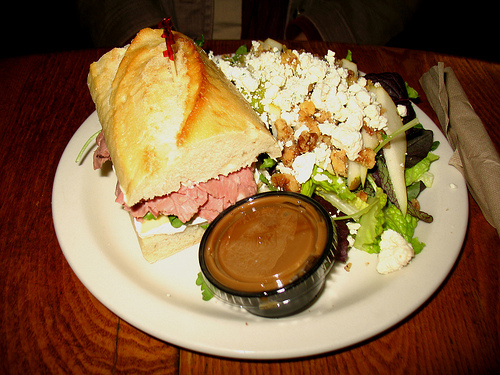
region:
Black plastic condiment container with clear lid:
[195, 188, 335, 318]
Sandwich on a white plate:
[83, 27, 282, 263]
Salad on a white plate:
[263, 39, 435, 267]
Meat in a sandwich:
[128, 167, 262, 224]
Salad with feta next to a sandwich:
[211, 48, 386, 183]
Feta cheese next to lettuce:
[371, 229, 417, 276]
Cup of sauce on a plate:
[201, 193, 337, 320]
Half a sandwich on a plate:
[85, 13, 277, 263]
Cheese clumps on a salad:
[225, 48, 363, 151]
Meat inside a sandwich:
[154, 184, 247, 220]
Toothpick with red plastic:
[159, 13, 179, 79]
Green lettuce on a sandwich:
[151, 212, 186, 231]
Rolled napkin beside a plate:
[430, 56, 499, 228]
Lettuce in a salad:
[358, 198, 423, 243]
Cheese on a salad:
[371, 75, 411, 212]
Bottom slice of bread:
[135, 228, 202, 262]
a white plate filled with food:
[50, 47, 470, 362]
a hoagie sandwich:
[89, 17, 259, 230]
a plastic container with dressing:
[202, 194, 335, 316]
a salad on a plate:
[217, 52, 424, 245]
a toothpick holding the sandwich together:
[160, 18, 181, 75]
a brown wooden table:
[5, 31, 499, 374]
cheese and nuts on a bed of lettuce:
[230, 49, 409, 199]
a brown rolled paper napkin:
[424, 56, 497, 228]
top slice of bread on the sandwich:
[96, 27, 271, 198]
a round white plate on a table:
[42, 38, 473, 365]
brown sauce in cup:
[186, 211, 308, 323]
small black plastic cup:
[204, 188, 314, 308]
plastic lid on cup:
[138, 193, 346, 301]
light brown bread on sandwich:
[129, 37, 225, 248]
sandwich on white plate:
[9, 37, 402, 338]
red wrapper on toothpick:
[156, 28, 198, 81]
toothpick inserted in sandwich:
[131, 3, 208, 138]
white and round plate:
[46, 79, 462, 343]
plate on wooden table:
[24, 39, 449, 343]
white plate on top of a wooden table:
[49, 56, 470, 358]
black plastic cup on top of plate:
[193, 189, 340, 316]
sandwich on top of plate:
[81, 25, 284, 263]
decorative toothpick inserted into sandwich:
[160, 14, 178, 79]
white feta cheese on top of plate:
[376, 228, 413, 272]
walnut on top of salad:
[270, 173, 297, 192]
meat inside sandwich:
[113, 169, 257, 222]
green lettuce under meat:
[144, 212, 208, 229]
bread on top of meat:
[83, 27, 278, 208]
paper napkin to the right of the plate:
[419, 64, 498, 224]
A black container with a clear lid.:
[195, 190, 335, 315]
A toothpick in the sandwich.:
[158, 15, 180, 74]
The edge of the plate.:
[138, 298, 190, 337]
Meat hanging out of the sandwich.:
[93, 128, 110, 173]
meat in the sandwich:
[131, 171, 245, 235]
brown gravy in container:
[198, 171, 340, 312]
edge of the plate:
[23, 149, 108, 276]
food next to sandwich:
[241, 48, 440, 187]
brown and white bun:
[104, 28, 226, 150]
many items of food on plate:
[56, 23, 425, 287]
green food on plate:
[338, 188, 415, 260]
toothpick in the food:
[137, 15, 189, 79]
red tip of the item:
[143, 13, 191, 65]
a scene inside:
[6, 1, 483, 373]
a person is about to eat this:
[27, 10, 478, 373]